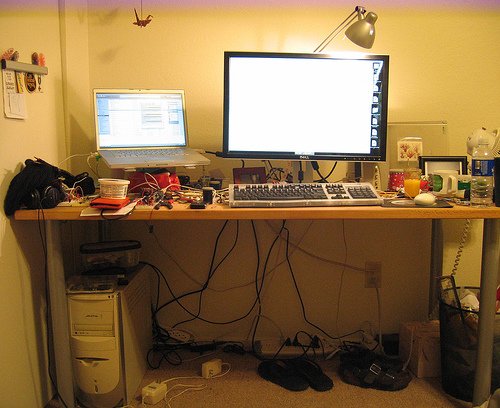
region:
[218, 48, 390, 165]
Large flat screen monitor on the center of the desk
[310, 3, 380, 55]
Chrome light on top of the flatscreen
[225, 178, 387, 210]
Keyboard in the center of the desk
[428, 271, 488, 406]
Black wire trash can with garbage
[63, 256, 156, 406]
White tower sitting under the desk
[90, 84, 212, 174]
Open laptop on the desk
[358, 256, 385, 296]
Power outlet under the desk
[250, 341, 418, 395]
Two pairs of black shoes under the desk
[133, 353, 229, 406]
Two white power cords unplugged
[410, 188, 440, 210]
White mouse sitting on the desk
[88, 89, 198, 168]
laptop on the desk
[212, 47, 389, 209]
computer on the desk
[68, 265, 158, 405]
cpu on the floor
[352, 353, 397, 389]
sandals on the floor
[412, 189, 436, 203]
mouse on mousepad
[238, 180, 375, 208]
keyboard at the screen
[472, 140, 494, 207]
water bottle on the desk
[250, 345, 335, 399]
flip flops on the floor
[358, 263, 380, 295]
electrical outlet on wall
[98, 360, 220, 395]
cables on the floor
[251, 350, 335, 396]
black slippers under a desk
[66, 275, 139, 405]
a computer tower under a desk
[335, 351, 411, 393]
brown slippers under a desk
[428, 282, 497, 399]
a black trash bin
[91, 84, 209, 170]
a laptop that is turned on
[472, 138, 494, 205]
a bottle of water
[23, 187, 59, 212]
black headphones under a cloth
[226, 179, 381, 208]
a white and gray keyboard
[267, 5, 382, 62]
a desk lamp shining on the monitor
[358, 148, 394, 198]
a speaker behind the monitor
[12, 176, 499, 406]
a brown desk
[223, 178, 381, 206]
a white computer keyboard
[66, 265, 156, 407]
a white computer cpu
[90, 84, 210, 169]
a gray laptop computer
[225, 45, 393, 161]
a large desktop monitor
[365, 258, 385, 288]
a beige outlet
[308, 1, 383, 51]
part of a gray table lamp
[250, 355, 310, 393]
a black flip flop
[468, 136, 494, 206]
a water bottle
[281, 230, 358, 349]
a long black cord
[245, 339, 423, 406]
sandals under the table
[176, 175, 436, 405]
sandals under the table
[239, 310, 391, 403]
the sandals are black